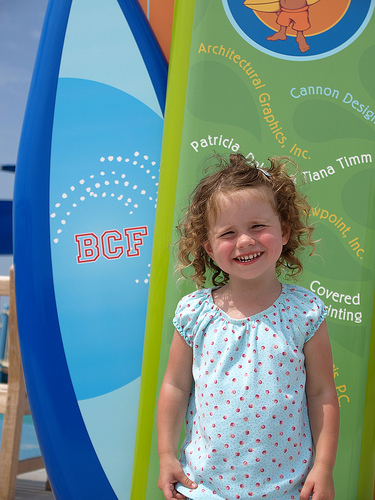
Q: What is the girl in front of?
A: Surfboards.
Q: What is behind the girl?
A: Surfboards.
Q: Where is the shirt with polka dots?
A: On the girl.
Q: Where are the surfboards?
A: Behind the girl.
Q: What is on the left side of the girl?
A: A light blue surfboard.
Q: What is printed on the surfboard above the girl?
A: A character.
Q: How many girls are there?
A: One.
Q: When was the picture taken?
A: Daytime.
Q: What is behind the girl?
A: Surfboards.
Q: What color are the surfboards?
A: Blue and green.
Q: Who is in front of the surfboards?
A: The girl.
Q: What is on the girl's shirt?
A: Polka dots.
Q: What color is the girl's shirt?
A: Red and white.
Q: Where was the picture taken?
A: At the beach.